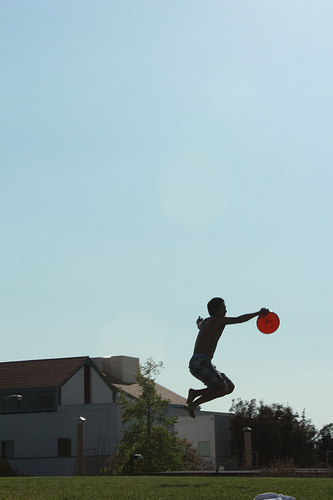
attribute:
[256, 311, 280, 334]
frisbee — orange, red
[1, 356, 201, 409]
roof — brown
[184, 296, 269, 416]
man — jumping, mid air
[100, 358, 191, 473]
tree — green, tall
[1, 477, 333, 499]
grass — green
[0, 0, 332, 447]
sky — blue, clear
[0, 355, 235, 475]
building — large